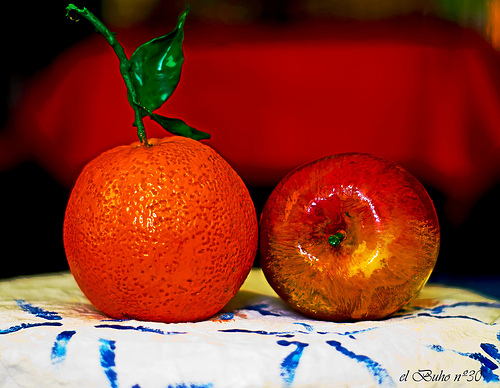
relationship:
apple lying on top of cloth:
[255, 151, 443, 323] [0, 268, 500, 387]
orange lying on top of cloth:
[57, 1, 259, 321] [0, 268, 500, 387]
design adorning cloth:
[1, 292, 186, 385] [0, 268, 500, 387]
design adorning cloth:
[219, 318, 394, 386] [0, 268, 500, 387]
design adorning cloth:
[219, 300, 395, 387] [0, 268, 500, 387]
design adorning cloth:
[402, 298, 484, 327] [0, 268, 500, 387]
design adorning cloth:
[423, 330, 484, 384] [0, 268, 500, 387]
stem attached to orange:
[63, 1, 150, 143] [57, 1, 259, 321]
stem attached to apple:
[327, 229, 344, 248] [255, 151, 443, 323]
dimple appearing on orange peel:
[184, 277, 192, 283] [58, 131, 258, 321]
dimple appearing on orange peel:
[199, 204, 205, 211] [58, 131, 258, 321]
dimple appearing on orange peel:
[158, 215, 164, 222] [58, 131, 258, 321]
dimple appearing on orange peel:
[140, 268, 145, 273] [58, 131, 258, 321]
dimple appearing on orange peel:
[110, 204, 116, 209] [58, 131, 258, 321]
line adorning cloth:
[325, 338, 396, 386] [1, 268, 484, 386]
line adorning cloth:
[275, 337, 310, 386] [1, 268, 484, 386]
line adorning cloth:
[97, 336, 118, 386] [1, 268, 484, 386]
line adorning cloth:
[292, 319, 312, 329] [1, 268, 484, 386]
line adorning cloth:
[315, 322, 378, 341] [1, 268, 484, 386]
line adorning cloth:
[92, 322, 187, 336] [1, 268, 484, 386]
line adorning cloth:
[50, 330, 75, 365] [1, 268, 484, 386]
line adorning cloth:
[0, 318, 61, 335] [1, 268, 484, 386]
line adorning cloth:
[11, 296, 61, 319] [1, 268, 484, 386]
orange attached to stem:
[57, 1, 259, 321] [63, 1, 150, 143]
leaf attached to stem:
[126, 3, 191, 117] [63, 1, 150, 143]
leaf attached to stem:
[132, 98, 212, 141] [63, 1, 150, 143]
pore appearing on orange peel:
[185, 277, 193, 283] [58, 131, 258, 321]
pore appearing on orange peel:
[169, 190, 176, 196] [58, 131, 258, 321]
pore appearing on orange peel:
[157, 251, 163, 256] [58, 131, 258, 321]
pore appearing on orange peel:
[100, 250, 106, 254] [58, 131, 258, 321]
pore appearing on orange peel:
[110, 204, 116, 208] [58, 131, 258, 321]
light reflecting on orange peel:
[101, 170, 182, 248] [64, 131, 258, 321]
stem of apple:
[327, 229, 344, 248] [255, 151, 443, 323]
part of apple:
[297, 273, 358, 316] [255, 151, 443, 323]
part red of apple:
[261, 151, 440, 247] [255, 151, 443, 323]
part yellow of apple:
[259, 235, 436, 321] [255, 151, 443, 323]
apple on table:
[255, 151, 443, 323] [1, 265, 498, 385]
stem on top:
[63, 1, 150, 143] [101, 137, 213, 163]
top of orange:
[101, 137, 213, 163] [57, 1, 259, 321]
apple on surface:
[255, 151, 443, 323] [1, 267, 498, 382]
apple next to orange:
[255, 151, 443, 323] [57, 1, 259, 321]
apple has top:
[255, 151, 443, 323] [317, 214, 357, 263]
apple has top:
[255, 151, 443, 323] [315, 216, 356, 257]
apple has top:
[255, 142, 447, 332] [319, 216, 357, 257]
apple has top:
[255, 151, 443, 323] [319, 225, 348, 255]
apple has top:
[255, 142, 447, 332] [315, 214, 355, 259]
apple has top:
[255, 142, 447, 332] [319, 220, 355, 260]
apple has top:
[255, 142, 447, 332] [317, 222, 355, 256]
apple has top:
[255, 142, 447, 332] [315, 218, 358, 256]